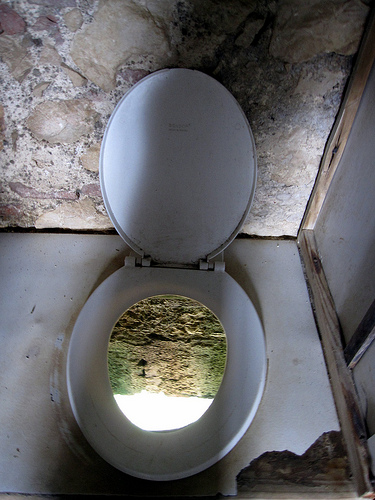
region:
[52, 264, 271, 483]
seat of open toilet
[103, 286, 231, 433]
picture inside of toilet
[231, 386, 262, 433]
light reflection on toilet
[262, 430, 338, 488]
broken surface around toilet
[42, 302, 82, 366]
white surface surrounding toilet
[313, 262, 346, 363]
wood board of frame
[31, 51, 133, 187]
stone wall behinf toilet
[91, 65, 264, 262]
inside of open cover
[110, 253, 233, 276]
mechanism attaching toilet cover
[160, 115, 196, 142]
faded name of toilet company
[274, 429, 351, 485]
Crack in a bathroom floor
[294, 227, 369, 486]
Wood plank on a bathroom floor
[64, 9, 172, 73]
rock in a wall of a bathroom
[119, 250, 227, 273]
Hinged toilet seat lid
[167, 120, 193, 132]
Words on a toilet lid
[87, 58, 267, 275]
White toilet lid in the raised position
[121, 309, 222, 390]
Rock wall under a toilet seat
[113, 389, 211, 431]
Open area under a toilet seat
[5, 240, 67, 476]
White step on a toilet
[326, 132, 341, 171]
Knot in a wooden plant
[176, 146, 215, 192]
part of a toilet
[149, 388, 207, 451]
part of a space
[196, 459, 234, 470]
edge of a toilet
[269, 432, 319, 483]
part of a stone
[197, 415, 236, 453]
part of a toilet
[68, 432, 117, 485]
part of a toilet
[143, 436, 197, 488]
edge of a toilet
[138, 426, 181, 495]
side of a toilet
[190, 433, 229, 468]
edge of a toilet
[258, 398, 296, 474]
part of a wall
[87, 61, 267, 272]
white plastic toilet lid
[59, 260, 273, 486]
white plastic toilet seat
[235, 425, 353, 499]
piece of wood as part of a floor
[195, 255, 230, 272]
toilet seat hinge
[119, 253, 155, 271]
white toilet seat hinge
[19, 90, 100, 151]
large stone in a wall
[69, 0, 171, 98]
large stone in a wall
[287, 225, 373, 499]
wood frame of a wall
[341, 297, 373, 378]
wood frame of a wall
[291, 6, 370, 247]
wood frame of a wall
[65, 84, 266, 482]
a white toilet seat and lid in an outside bathroom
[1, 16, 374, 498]
an outdoor bathroom portal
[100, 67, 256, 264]
the lid to a toilet seat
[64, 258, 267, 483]
a white toilet seat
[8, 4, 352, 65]
a stone wall behind the toilet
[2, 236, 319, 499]
a white toilet seat fitted on top of a wooden board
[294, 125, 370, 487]
a wood frame on the bathroom portal wall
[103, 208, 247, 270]
dirt on the toilet lid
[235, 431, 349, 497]
chipped paint on the board affixed to the toilet seat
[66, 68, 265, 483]
a toilet inside a portal bathroom